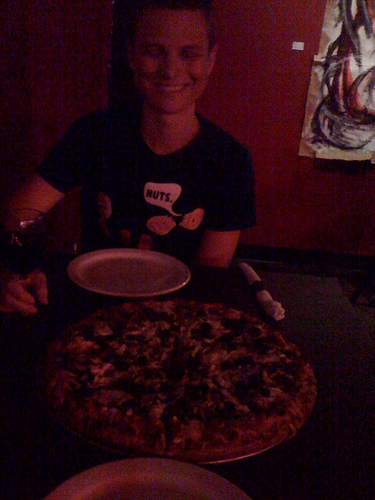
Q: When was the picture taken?
A: Before the pizza was eaten.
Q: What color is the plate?
A: White.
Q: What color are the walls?
A: Red.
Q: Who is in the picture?
A: A women.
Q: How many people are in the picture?
A: One.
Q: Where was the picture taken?
A: In a restaurant.